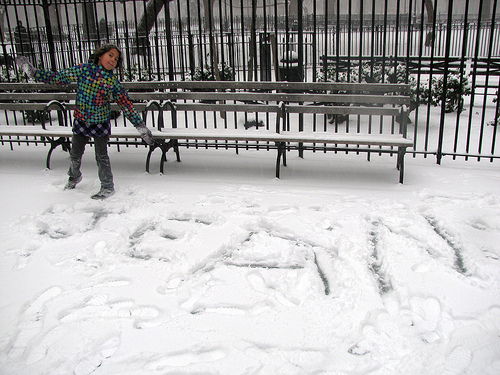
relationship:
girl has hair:
[17, 44, 151, 198] [88, 45, 123, 75]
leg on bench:
[395, 151, 408, 180] [3, 81, 413, 182]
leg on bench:
[274, 142, 289, 177] [3, 81, 413, 182]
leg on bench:
[158, 133, 182, 173] [3, 81, 413, 182]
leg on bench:
[146, 141, 159, 173] [3, 81, 413, 182]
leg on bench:
[49, 138, 61, 168] [3, 81, 413, 182]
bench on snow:
[3, 81, 413, 182] [1, 18, 496, 371]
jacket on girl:
[34, 63, 150, 127] [17, 44, 151, 198]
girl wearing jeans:
[17, 44, 151, 198] [67, 130, 117, 194]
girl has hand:
[17, 44, 151, 198] [136, 122, 155, 148]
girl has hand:
[17, 44, 151, 198] [12, 57, 37, 74]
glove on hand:
[138, 125, 155, 146] [136, 122, 155, 148]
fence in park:
[3, 0, 499, 158] [4, 1, 498, 372]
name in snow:
[34, 195, 497, 294] [1, 18, 496, 371]